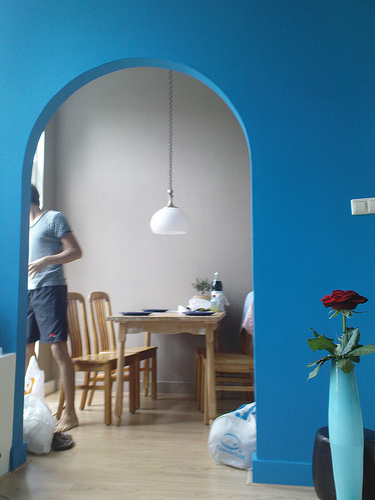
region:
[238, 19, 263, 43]
this is the wall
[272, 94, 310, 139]
the wall is blue in color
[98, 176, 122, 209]
this is a wall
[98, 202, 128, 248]
the wall is white in color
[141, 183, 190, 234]
this is a bulb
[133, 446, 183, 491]
this is the floor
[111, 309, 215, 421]
this is a table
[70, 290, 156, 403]
these are some chairs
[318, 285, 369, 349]
this is a rose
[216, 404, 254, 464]
this is a paper bag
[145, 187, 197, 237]
a light hanging from the ceiling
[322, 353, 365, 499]
a smokey blue vase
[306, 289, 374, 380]
a rose in a vase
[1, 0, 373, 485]
a blue wall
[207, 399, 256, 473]
a gray and blue bag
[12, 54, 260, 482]
an arched doorway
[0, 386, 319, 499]
a wooden dining room floor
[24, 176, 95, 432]
a man with bare feet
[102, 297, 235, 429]
a dining room table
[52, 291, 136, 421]
a wooden chair at a table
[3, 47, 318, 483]
Man looks outside from his dining room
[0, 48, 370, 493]
Man peers outside from his dining area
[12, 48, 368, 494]
Man prepares to take out garbage from his dining room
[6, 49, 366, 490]
Man puts down white plastic bag as he prepares to leave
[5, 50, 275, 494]
Man gets up from his dining table to take out garbage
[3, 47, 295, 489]
Man leaves white bag on the floor as he leaves dining room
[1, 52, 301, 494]
Man looks outside before leaving the room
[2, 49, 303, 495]
Man peers outside over his shoulder as he stands barefoot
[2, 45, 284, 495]
Barefoot man stands next to his table and puts down plastic bag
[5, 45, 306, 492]
Man puts down plastic bag and peers out window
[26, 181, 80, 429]
a person in a dining room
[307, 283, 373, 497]
a rose in a vase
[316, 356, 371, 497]
the vase is blue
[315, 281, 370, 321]
the rose is red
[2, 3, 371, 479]
the wall is blue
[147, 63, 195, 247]
a light hanging down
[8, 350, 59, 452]
a bag on the ground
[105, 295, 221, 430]
a table in the dining room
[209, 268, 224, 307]
a bottle on the table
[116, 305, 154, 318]
a blue plate on the table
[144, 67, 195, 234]
White and silver hanging lamp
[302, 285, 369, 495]
Red rose in a blue vase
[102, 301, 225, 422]
Kitchen table with plates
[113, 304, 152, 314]
Plate on a table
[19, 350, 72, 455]
Shopping bags and shoes on kitchen floor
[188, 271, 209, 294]
Miniature decorative tree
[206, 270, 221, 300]
Soda bottle with white cap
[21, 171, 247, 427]
Man walking in a kitchen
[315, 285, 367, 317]
Head of a red rose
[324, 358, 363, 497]
A blue flower vase